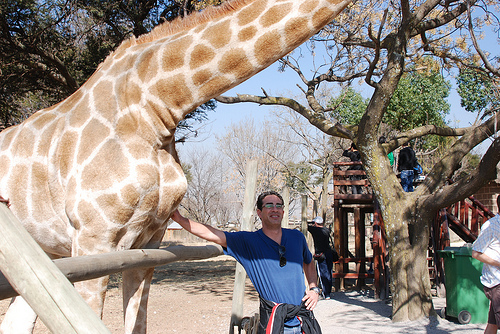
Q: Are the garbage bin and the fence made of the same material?
A: No, the garbage bin is made of plastic and the fence is made of wood.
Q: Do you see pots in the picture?
A: No, there are no pots.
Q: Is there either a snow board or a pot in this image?
A: No, there are no pots or snowboards.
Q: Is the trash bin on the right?
A: Yes, the trash bin is on the right of the image.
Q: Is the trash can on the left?
A: No, the trash can is on the right of the image.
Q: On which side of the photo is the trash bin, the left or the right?
A: The trash bin is on the right of the image.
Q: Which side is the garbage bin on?
A: The garbage bin is on the right of the image.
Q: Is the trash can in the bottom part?
A: Yes, the trash can is in the bottom of the image.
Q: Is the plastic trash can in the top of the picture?
A: No, the trashcan is in the bottom of the image.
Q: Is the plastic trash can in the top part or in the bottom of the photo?
A: The trash can is in the bottom of the image.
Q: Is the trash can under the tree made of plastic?
A: Yes, the garbage can is made of plastic.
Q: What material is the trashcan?
A: The trashcan is made of plastic.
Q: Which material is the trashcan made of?
A: The trashcan is made of plastic.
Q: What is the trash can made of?
A: The trashcan is made of plastic.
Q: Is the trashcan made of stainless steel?
A: No, the trashcan is made of plastic.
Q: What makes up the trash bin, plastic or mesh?
A: The trash bin is made of plastic.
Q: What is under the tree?
A: The trash bin is under the tree.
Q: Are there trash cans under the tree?
A: Yes, there is a trash can under the tree.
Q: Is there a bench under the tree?
A: No, there is a trash can under the tree.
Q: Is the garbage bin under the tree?
A: Yes, the garbage bin is under the tree.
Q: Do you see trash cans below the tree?
A: Yes, there is a trash can below the tree.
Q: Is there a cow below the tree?
A: No, there is a trash can below the tree.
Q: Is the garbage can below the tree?
A: Yes, the garbage can is below the tree.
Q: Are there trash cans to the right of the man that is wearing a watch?
A: Yes, there is a trash can to the right of the man.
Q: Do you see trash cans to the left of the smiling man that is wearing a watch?
A: No, the trash can is to the right of the man.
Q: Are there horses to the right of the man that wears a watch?
A: No, there is a trash can to the right of the man.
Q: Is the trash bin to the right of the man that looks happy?
A: Yes, the trash bin is to the right of the man.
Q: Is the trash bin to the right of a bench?
A: No, the trash bin is to the right of the man.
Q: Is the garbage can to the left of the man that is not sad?
A: No, the garbage can is to the right of the man.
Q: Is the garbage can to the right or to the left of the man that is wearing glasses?
A: The garbage can is to the right of the man.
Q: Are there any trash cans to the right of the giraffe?
A: Yes, there is a trash can to the right of the giraffe.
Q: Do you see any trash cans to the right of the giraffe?
A: Yes, there is a trash can to the right of the giraffe.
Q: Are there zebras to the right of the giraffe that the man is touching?
A: No, there is a trash can to the right of the giraffe.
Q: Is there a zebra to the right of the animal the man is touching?
A: No, there is a trash can to the right of the giraffe.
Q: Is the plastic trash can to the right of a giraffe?
A: Yes, the garbage can is to the right of a giraffe.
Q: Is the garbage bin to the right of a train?
A: No, the garbage bin is to the right of a giraffe.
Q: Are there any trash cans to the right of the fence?
A: Yes, there is a trash can to the right of the fence.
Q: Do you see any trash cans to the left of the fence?
A: No, the trash can is to the right of the fence.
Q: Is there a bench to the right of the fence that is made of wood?
A: No, there is a trash can to the right of the fence.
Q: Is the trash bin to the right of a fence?
A: Yes, the trash bin is to the right of a fence.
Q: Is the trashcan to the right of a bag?
A: No, the trashcan is to the right of a fence.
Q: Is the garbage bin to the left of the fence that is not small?
A: No, the garbage bin is to the right of the fence.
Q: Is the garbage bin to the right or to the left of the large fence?
A: The garbage bin is to the right of the fence.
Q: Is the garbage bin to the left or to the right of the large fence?
A: The garbage bin is to the right of the fence.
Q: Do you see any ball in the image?
A: No, there are no balls.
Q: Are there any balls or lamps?
A: No, there are no balls or lamps.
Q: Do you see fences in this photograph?
A: Yes, there is a fence.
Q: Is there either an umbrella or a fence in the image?
A: Yes, there is a fence.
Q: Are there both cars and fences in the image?
A: No, there is a fence but no cars.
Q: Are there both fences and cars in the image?
A: No, there is a fence but no cars.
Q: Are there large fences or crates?
A: Yes, there is a large fence.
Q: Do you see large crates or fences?
A: Yes, there is a large fence.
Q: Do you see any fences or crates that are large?
A: Yes, the fence is large.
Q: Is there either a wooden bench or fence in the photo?
A: Yes, there is a wood fence.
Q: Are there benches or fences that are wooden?
A: Yes, the fence is wooden.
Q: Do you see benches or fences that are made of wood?
A: Yes, the fence is made of wood.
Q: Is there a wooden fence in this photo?
A: Yes, there is a wood fence.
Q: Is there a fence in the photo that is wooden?
A: Yes, there is a fence that is wooden.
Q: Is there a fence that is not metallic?
A: Yes, there is a wooden fence.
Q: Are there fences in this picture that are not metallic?
A: Yes, there is a wooden fence.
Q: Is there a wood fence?
A: Yes, there is a fence that is made of wood.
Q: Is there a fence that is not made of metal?
A: Yes, there is a fence that is made of wood.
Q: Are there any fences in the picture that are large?
A: Yes, there is a large fence.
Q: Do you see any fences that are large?
A: Yes, there is a fence that is large.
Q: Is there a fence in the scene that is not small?
A: Yes, there is a large fence.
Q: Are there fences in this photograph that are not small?
A: Yes, there is a large fence.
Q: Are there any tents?
A: No, there are no tents.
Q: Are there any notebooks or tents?
A: No, there are no tents or notebooks.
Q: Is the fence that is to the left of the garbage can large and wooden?
A: Yes, the fence is large and wooden.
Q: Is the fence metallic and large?
A: No, the fence is large but wooden.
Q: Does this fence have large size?
A: Yes, the fence is large.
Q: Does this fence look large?
A: Yes, the fence is large.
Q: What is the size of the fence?
A: The fence is large.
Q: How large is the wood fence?
A: The fence is large.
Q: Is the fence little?
A: No, the fence is large.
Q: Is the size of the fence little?
A: No, the fence is large.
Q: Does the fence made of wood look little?
A: No, the fence is large.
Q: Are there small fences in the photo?
A: No, there is a fence but it is large.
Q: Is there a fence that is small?
A: No, there is a fence but it is large.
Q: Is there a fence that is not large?
A: No, there is a fence but it is large.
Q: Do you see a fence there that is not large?
A: No, there is a fence but it is large.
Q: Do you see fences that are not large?
A: No, there is a fence but it is large.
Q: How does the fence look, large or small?
A: The fence is large.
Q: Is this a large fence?
A: Yes, this is a large fence.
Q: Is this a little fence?
A: No, this is a large fence.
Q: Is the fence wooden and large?
A: Yes, the fence is wooden and large.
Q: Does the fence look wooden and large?
A: Yes, the fence is wooden and large.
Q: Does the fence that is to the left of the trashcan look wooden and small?
A: No, the fence is wooden but large.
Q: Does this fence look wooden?
A: Yes, the fence is wooden.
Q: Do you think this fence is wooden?
A: Yes, the fence is wooden.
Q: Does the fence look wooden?
A: Yes, the fence is wooden.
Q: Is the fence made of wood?
A: Yes, the fence is made of wood.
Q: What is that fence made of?
A: The fence is made of wood.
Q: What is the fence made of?
A: The fence is made of wood.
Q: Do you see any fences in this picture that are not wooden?
A: No, there is a fence but it is wooden.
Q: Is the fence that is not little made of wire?
A: No, the fence is made of wood.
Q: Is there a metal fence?
A: No, there is a fence but it is made of wood.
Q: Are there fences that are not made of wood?
A: No, there is a fence but it is made of wood.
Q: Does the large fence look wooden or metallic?
A: The fence is wooden.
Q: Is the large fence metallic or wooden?
A: The fence is wooden.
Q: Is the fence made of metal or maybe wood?
A: The fence is made of wood.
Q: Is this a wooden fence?
A: Yes, this is a wooden fence.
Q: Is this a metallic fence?
A: No, this is a wooden fence.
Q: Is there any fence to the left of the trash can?
A: Yes, there is a fence to the left of the trash can.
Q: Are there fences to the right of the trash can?
A: No, the fence is to the left of the trash can.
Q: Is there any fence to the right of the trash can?
A: No, the fence is to the left of the trash can.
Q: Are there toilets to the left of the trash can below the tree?
A: No, there is a fence to the left of the garbage can.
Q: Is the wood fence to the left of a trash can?
A: Yes, the fence is to the left of a trash can.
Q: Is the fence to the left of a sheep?
A: No, the fence is to the left of a trash can.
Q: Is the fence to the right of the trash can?
A: No, the fence is to the left of the trash can.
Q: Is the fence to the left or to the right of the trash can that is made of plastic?
A: The fence is to the left of the trashcan.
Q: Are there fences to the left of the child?
A: Yes, there is a fence to the left of the child.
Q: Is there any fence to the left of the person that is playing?
A: Yes, there is a fence to the left of the child.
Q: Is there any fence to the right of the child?
A: No, the fence is to the left of the child.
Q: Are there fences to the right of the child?
A: No, the fence is to the left of the child.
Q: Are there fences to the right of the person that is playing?
A: No, the fence is to the left of the child.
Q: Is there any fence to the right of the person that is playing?
A: No, the fence is to the left of the child.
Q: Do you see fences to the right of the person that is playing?
A: No, the fence is to the left of the child.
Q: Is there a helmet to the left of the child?
A: No, there is a fence to the left of the child.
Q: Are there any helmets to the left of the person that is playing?
A: No, there is a fence to the left of the child.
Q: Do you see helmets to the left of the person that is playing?
A: No, there is a fence to the left of the child.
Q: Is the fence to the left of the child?
A: Yes, the fence is to the left of the child.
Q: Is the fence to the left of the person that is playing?
A: Yes, the fence is to the left of the child.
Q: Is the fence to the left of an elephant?
A: No, the fence is to the left of the child.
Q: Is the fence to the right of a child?
A: No, the fence is to the left of a child.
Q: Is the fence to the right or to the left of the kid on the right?
A: The fence is to the left of the child.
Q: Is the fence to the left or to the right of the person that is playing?
A: The fence is to the left of the child.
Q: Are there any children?
A: Yes, there is a child.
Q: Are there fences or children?
A: Yes, there is a child.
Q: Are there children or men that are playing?
A: Yes, the child is playing.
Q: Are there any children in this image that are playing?
A: Yes, there is a child that is playing.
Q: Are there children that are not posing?
A: Yes, there is a child that is playing.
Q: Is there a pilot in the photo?
A: No, there are no pilots.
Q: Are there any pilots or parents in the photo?
A: No, there are no pilots or parents.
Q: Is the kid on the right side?
A: Yes, the kid is on the right of the image.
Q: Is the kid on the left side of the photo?
A: No, the kid is on the right of the image.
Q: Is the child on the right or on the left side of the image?
A: The child is on the right of the image.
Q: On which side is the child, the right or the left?
A: The child is on the right of the image.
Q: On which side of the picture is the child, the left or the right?
A: The child is on the right of the image.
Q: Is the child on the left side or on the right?
A: The child is on the right of the image.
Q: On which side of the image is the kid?
A: The kid is on the right of the image.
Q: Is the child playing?
A: Yes, the child is playing.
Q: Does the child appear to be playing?
A: Yes, the child is playing.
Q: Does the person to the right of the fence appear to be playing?
A: Yes, the child is playing.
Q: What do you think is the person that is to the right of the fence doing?
A: The child is playing.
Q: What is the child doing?
A: The child is playing.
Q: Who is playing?
A: The child is playing.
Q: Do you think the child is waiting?
A: No, the child is playing.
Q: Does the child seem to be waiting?
A: No, the child is playing.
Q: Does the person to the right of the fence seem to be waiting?
A: No, the child is playing.